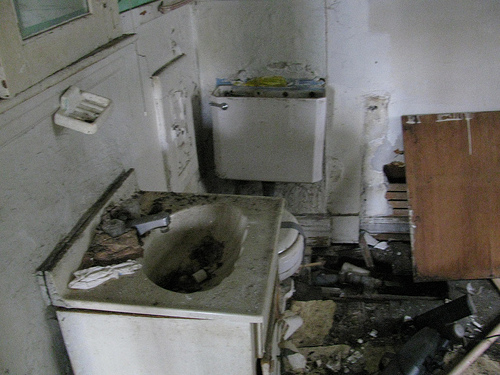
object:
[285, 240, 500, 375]
floor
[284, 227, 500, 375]
junk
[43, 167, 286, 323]
counter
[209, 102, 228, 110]
silver handle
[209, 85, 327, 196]
toilet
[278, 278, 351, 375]
debris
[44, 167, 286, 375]
basin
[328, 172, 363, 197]
ground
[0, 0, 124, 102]
window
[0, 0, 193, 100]
white frame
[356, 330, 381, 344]
rubble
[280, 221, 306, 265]
tape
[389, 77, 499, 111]
wall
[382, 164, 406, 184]
hole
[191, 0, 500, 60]
wall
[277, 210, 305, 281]
toilet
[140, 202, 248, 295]
sink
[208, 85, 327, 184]
tank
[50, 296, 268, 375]
paint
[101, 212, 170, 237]
faucet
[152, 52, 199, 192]
wall panel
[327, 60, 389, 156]
drywall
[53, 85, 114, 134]
dish